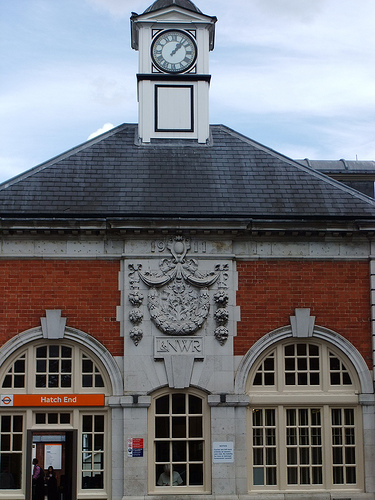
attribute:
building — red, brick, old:
[6, 4, 371, 492]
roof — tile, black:
[5, 123, 370, 219]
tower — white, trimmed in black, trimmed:
[131, 3, 215, 145]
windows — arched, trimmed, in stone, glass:
[3, 307, 372, 496]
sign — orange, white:
[13, 393, 105, 409]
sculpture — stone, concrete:
[117, 238, 241, 393]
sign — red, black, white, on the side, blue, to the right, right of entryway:
[126, 437, 147, 460]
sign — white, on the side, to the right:
[211, 440, 236, 465]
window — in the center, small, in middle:
[149, 385, 213, 495]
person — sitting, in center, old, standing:
[158, 463, 185, 485]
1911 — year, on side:
[147, 235, 209, 256]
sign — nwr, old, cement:
[156, 337, 204, 358]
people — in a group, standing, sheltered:
[34, 456, 72, 496]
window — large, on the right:
[253, 335, 365, 495]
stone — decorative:
[290, 306, 317, 339]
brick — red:
[271, 283, 280, 288]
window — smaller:
[2, 413, 26, 452]